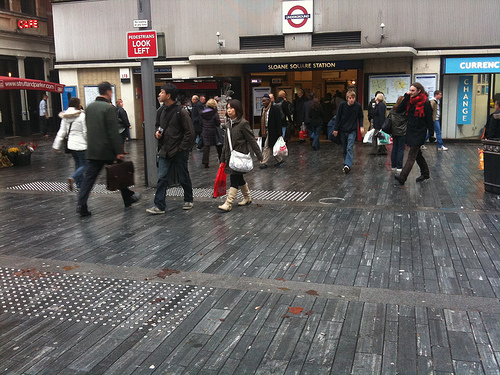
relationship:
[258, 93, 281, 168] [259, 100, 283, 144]
man in jacket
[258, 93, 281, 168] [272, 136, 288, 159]
man carrying bags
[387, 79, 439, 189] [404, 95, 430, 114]
man in scarf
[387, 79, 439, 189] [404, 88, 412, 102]
man on phone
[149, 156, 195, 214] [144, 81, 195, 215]
pants on man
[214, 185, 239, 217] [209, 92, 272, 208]
boots on woman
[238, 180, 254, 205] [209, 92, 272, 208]
boots on woman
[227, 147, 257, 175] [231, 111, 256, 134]
pocketbook on shoulder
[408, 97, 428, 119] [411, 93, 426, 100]
scarf on neck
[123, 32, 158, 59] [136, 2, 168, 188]
red sign on post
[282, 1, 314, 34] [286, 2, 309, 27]
sign with circle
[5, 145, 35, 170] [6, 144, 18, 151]
pot with flowers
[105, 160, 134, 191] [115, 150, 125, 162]
brief case in hand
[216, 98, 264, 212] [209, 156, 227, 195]
woman carrying bag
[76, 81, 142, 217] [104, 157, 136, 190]
man carrying briefcase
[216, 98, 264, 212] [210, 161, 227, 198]
woman holding bag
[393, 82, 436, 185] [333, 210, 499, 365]
man walking on sidewalk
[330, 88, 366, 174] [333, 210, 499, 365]
man walking on sidewalk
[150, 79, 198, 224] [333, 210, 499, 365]
man walking on sidewalk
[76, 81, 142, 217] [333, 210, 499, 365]
man walking on sidewalk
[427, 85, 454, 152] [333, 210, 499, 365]
man walking on sidewalk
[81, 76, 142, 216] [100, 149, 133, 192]
man carrying brief case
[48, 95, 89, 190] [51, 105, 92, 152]
lady wearing jacket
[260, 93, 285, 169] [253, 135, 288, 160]
man holding bags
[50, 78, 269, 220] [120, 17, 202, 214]
people walking around pole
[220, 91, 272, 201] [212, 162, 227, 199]
woman carrying bag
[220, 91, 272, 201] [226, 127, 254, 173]
woman carrying pocketbook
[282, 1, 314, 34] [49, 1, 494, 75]
sign over roof